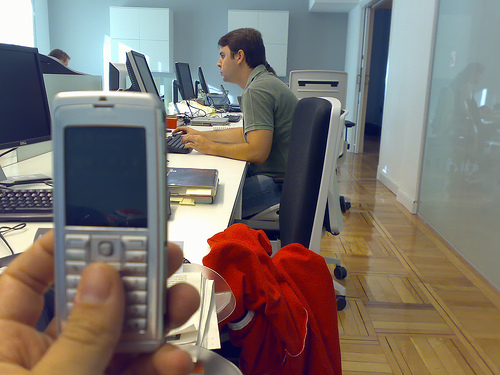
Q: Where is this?
A: This is at the office.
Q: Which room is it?
A: It is an office.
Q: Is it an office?
A: Yes, it is an office.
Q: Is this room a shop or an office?
A: It is an office.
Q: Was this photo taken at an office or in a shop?
A: It was taken at an office.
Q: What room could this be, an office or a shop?
A: It is an office.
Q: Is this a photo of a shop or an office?
A: It is showing an office.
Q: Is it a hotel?
A: No, it is an office.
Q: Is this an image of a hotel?
A: No, the picture is showing an office.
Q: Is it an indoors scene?
A: Yes, it is indoors.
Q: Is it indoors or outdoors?
A: It is indoors.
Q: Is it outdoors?
A: No, it is indoors.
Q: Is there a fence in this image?
A: No, there are no fences.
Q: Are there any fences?
A: No, there are no fences.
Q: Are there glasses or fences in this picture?
A: No, there are no fences or glasses.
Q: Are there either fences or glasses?
A: No, there are no fences or glasses.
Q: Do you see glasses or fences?
A: No, there are no fences or glasses.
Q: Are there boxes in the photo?
A: No, there are no boxes.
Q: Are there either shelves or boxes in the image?
A: No, there are no boxes or shelves.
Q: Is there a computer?
A: Yes, there is a computer.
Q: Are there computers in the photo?
A: Yes, there is a computer.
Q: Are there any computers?
A: Yes, there is a computer.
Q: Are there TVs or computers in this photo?
A: Yes, there is a computer.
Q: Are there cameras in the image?
A: No, there are no cameras.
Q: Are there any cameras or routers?
A: No, there are no cameras or routers.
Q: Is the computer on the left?
A: Yes, the computer is on the left of the image.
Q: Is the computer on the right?
A: No, the computer is on the left of the image.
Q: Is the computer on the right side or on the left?
A: The computer is on the left of the image.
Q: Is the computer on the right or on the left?
A: The computer is on the left of the image.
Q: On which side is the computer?
A: The computer is on the left of the image.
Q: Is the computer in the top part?
A: Yes, the computer is in the top of the image.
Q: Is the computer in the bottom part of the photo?
A: No, the computer is in the top of the image.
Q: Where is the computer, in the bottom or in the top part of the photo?
A: The computer is in the top of the image.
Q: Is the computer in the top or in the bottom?
A: The computer is in the top of the image.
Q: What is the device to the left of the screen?
A: The device is a computer.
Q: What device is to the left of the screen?
A: The device is a computer.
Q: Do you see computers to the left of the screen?
A: Yes, there is a computer to the left of the screen.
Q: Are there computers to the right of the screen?
A: No, the computer is to the left of the screen.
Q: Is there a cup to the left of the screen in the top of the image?
A: No, there is a computer to the left of the screen.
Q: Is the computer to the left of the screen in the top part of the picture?
A: Yes, the computer is to the left of the screen.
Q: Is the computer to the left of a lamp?
A: No, the computer is to the left of the screen.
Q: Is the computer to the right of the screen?
A: No, the computer is to the left of the screen.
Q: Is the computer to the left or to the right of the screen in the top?
A: The computer is to the left of the screen.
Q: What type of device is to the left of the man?
A: The device is a computer.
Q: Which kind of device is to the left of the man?
A: The device is a computer.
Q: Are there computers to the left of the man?
A: Yes, there is a computer to the left of the man.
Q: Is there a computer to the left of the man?
A: Yes, there is a computer to the left of the man.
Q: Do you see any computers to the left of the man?
A: Yes, there is a computer to the left of the man.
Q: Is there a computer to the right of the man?
A: No, the computer is to the left of the man.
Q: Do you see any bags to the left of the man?
A: No, there is a computer to the left of the man.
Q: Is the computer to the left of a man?
A: Yes, the computer is to the left of a man.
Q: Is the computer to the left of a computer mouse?
A: No, the computer is to the left of a man.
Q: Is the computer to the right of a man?
A: No, the computer is to the left of a man.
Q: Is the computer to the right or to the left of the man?
A: The computer is to the left of the man.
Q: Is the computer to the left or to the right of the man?
A: The computer is to the left of the man.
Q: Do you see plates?
A: No, there are no plates.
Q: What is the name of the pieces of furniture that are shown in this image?
A: The pieces of furniture are chairs.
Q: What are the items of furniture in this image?
A: The pieces of furniture are chairs.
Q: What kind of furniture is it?
A: The pieces of furniture are chairs.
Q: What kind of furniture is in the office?
A: The pieces of furniture are chairs.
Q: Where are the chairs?
A: The chairs are in the office.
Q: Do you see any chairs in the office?
A: Yes, there are chairs in the office.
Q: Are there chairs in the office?
A: Yes, there are chairs in the office.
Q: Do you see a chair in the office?
A: Yes, there are chairs in the office.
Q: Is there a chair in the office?
A: Yes, there are chairs in the office.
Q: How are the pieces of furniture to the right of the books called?
A: The pieces of furniture are chairs.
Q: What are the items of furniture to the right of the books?
A: The pieces of furniture are chairs.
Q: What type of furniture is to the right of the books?
A: The pieces of furniture are chairs.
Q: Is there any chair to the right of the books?
A: Yes, there are chairs to the right of the books.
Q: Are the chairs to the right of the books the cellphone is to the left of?
A: Yes, the chairs are to the right of the books.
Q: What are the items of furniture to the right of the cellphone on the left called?
A: The pieces of furniture are chairs.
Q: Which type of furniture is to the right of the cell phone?
A: The pieces of furniture are chairs.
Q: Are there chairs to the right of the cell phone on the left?
A: Yes, there are chairs to the right of the cellphone.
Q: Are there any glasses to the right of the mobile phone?
A: No, there are chairs to the right of the mobile phone.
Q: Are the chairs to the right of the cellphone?
A: Yes, the chairs are to the right of the cellphone.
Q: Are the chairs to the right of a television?
A: No, the chairs are to the right of the cellphone.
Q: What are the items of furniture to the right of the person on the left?
A: The pieces of furniture are chairs.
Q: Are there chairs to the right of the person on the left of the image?
A: Yes, there are chairs to the right of the person.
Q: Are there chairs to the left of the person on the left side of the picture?
A: No, the chairs are to the right of the person.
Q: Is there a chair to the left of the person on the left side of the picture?
A: No, the chairs are to the right of the person.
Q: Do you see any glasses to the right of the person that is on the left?
A: No, there are chairs to the right of the person.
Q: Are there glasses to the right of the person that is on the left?
A: No, there are chairs to the right of the person.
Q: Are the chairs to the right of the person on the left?
A: Yes, the chairs are to the right of the person.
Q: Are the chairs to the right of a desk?
A: No, the chairs are to the right of the person.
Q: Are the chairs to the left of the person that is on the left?
A: No, the chairs are to the right of the person.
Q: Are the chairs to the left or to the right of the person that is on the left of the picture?
A: The chairs are to the right of the person.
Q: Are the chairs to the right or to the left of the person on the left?
A: The chairs are to the right of the person.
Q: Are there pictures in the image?
A: No, there are no pictures.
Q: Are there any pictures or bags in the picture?
A: No, there are no pictures or bags.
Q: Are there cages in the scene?
A: No, there are no cages.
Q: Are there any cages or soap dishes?
A: No, there are no cages or soap dishes.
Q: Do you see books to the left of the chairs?
A: Yes, there are books to the left of the chairs.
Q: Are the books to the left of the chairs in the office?
A: Yes, the books are to the left of the chairs.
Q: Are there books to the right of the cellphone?
A: Yes, there are books to the right of the cellphone.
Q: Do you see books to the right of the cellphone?
A: Yes, there are books to the right of the cellphone.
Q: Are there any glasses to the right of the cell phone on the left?
A: No, there are books to the right of the cell phone.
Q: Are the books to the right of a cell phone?
A: Yes, the books are to the right of a cell phone.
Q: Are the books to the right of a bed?
A: No, the books are to the right of a cell phone.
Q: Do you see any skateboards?
A: No, there are no skateboards.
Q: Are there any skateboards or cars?
A: No, there are no skateboards or cars.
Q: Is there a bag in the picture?
A: No, there are no bags.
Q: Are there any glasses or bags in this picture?
A: No, there are no bags or glasses.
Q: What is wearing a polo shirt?
A: The jacket is wearing a polo shirt.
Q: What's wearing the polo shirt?
A: The jacket is wearing a polo shirt.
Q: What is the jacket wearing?
A: The jacket is wearing a polo shirt.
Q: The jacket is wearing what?
A: The jacket is wearing a polo shirt.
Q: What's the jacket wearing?
A: The jacket is wearing a polo shirt.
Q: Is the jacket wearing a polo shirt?
A: Yes, the jacket is wearing a polo shirt.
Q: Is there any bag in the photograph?
A: No, there are no bags.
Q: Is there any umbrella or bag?
A: No, there are no bags or umbrellas.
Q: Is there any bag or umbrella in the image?
A: No, there are no bags or umbrellas.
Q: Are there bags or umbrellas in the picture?
A: No, there are no bags or umbrellas.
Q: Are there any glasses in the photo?
A: No, there are no glasses.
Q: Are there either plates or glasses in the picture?
A: No, there are no glasses or plates.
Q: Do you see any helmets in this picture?
A: No, there are no helmets.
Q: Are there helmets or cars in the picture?
A: No, there are no helmets or cars.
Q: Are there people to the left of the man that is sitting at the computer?
A: Yes, there is a person to the left of the man.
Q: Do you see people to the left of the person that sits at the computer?
A: Yes, there is a person to the left of the man.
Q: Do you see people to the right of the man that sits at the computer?
A: No, the person is to the left of the man.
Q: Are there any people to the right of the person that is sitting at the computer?
A: No, the person is to the left of the man.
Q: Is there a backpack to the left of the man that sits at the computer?
A: No, there is a person to the left of the man.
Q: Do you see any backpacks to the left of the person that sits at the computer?
A: No, there is a person to the left of the man.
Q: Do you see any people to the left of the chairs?
A: Yes, there is a person to the left of the chairs.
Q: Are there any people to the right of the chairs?
A: No, the person is to the left of the chairs.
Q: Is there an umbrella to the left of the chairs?
A: No, there is a person to the left of the chairs.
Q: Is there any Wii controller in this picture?
A: No, there are no Wii controllers.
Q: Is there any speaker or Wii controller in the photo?
A: No, there are no Wii controllers or speakers.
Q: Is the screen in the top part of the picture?
A: Yes, the screen is in the top of the image.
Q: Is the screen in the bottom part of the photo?
A: No, the screen is in the top of the image.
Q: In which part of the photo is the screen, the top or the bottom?
A: The screen is in the top of the image.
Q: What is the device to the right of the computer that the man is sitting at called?
A: The device is a screen.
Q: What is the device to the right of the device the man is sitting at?
A: The device is a screen.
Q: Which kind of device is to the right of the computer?
A: The device is a screen.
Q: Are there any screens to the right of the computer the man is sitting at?
A: Yes, there is a screen to the right of the computer.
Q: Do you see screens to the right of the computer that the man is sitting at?
A: Yes, there is a screen to the right of the computer.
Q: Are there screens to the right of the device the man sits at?
A: Yes, there is a screen to the right of the computer.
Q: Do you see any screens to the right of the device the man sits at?
A: Yes, there is a screen to the right of the computer.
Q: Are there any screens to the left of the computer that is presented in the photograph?
A: No, the screen is to the right of the computer.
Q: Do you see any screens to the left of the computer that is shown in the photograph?
A: No, the screen is to the right of the computer.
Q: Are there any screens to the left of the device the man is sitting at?
A: No, the screen is to the right of the computer.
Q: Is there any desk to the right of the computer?
A: No, there is a screen to the right of the computer.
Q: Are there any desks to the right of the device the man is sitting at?
A: No, there is a screen to the right of the computer.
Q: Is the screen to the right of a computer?
A: Yes, the screen is to the right of a computer.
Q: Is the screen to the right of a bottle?
A: No, the screen is to the right of a computer.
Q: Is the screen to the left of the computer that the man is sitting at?
A: No, the screen is to the right of the computer.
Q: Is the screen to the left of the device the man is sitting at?
A: No, the screen is to the right of the computer.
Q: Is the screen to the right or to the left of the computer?
A: The screen is to the right of the computer.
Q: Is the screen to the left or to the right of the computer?
A: The screen is to the right of the computer.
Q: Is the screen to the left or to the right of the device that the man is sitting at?
A: The screen is to the right of the computer.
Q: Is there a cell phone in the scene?
A: Yes, there is a cell phone.